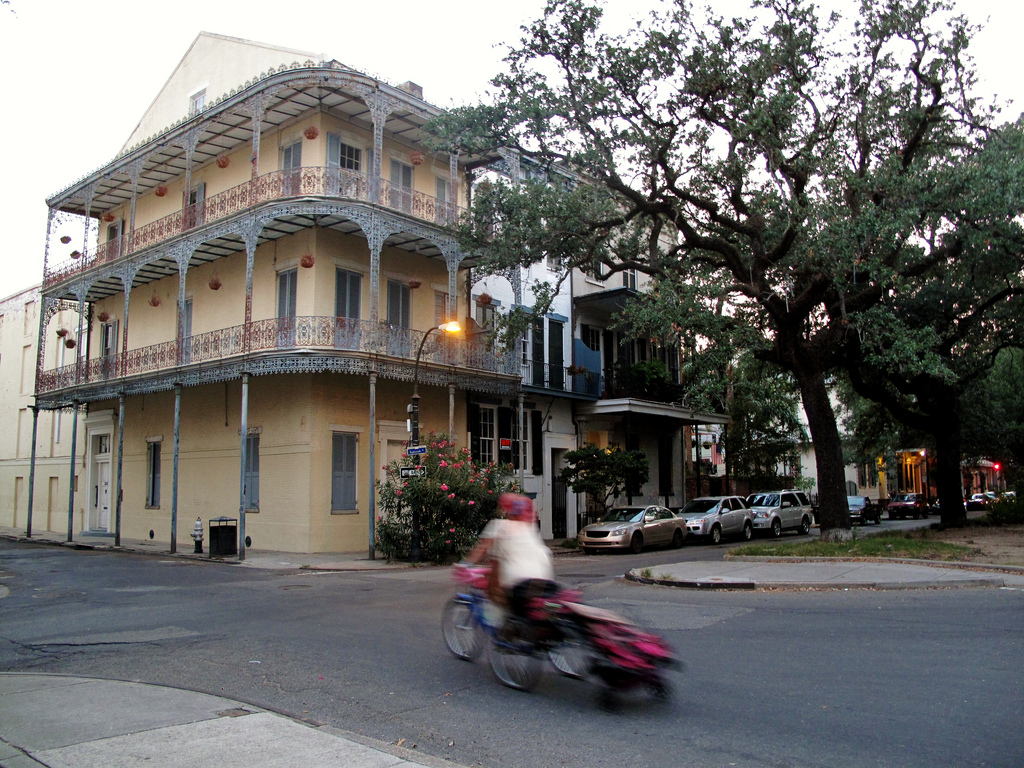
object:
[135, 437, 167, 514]
window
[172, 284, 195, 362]
window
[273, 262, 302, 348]
window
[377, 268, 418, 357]
window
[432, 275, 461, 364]
window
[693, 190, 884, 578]
building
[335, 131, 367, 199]
window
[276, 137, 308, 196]
window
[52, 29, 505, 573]
house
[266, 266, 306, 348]
window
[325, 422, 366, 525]
window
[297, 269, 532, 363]
balcony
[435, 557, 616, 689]
tricycle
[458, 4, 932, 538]
tree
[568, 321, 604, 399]
wall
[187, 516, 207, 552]
hydrant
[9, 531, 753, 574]
sidewalk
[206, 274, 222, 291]
ball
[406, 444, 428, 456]
sign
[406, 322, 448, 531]
pole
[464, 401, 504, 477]
frame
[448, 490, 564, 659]
person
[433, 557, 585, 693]
bike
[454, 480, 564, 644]
man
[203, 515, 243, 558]
trash can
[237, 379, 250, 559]
pole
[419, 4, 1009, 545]
tree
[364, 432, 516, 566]
plant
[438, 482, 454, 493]
flowers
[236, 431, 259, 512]
window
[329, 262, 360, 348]
window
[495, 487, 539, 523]
hat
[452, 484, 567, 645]
girl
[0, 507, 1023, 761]
road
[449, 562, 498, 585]
cloth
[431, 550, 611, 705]
cycle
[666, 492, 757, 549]
cars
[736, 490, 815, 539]
cars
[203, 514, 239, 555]
trash can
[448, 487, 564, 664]
person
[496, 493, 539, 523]
helmet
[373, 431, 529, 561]
rose bush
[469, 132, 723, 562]
building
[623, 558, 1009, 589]
curb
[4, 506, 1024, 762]
street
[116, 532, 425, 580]
curb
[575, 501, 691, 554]
car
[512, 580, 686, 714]
trailer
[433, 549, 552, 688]
tricycle